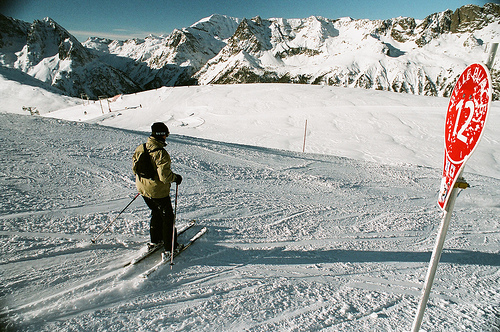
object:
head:
[151, 122, 171, 140]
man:
[132, 122, 184, 251]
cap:
[149, 122, 171, 139]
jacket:
[131, 136, 176, 200]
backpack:
[134, 142, 166, 184]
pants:
[136, 195, 182, 251]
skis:
[130, 219, 210, 282]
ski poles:
[167, 176, 186, 271]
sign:
[437, 63, 494, 214]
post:
[408, 41, 500, 331]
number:
[450, 98, 466, 137]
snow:
[0, 83, 498, 330]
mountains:
[1, 5, 499, 96]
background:
[1, 1, 499, 115]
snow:
[230, 190, 500, 330]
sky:
[1, 2, 301, 17]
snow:
[7, 14, 488, 82]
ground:
[0, 116, 495, 332]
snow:
[42, 245, 120, 274]